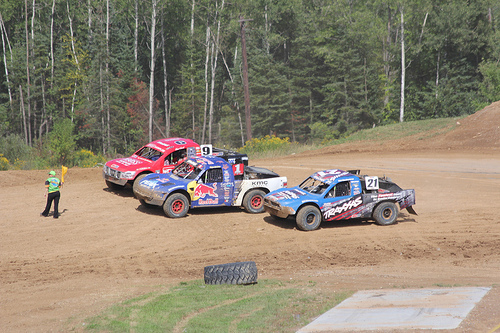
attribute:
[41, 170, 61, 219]
man — wearing green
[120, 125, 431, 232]
cars — lined up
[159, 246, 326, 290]
tire — black 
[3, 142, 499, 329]
race track — dirt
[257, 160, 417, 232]
truck — white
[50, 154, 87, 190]
flag — yellow 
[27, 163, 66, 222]
person — standing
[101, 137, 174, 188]
car — number 6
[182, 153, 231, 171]
top — blue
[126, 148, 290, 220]
truck — blue, white, red, yellow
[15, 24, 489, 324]
background — white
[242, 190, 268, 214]
wheel — red 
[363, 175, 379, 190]
number — white 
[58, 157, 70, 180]
flag — yellow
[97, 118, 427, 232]
trucks — lined up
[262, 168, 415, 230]
racing truck — black 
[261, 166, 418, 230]
car — blue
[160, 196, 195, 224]
rims — red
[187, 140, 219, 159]
numbers — black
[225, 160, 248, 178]
number — white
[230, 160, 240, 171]
background — red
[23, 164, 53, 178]
cap — green